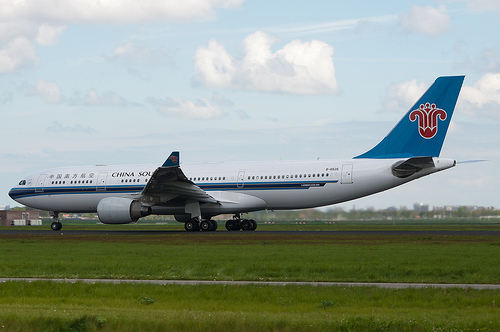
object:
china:
[111, 170, 138, 179]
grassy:
[3, 237, 499, 250]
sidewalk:
[0, 277, 496, 286]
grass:
[0, 237, 499, 329]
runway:
[4, 227, 499, 237]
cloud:
[193, 32, 335, 93]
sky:
[0, 0, 496, 74]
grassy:
[262, 220, 499, 231]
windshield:
[18, 179, 30, 187]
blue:
[63, 46, 107, 70]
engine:
[98, 197, 133, 225]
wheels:
[182, 220, 196, 232]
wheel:
[48, 221, 63, 228]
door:
[341, 164, 353, 183]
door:
[237, 171, 244, 189]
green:
[135, 293, 155, 304]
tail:
[352, 71, 471, 157]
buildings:
[7, 206, 28, 227]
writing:
[47, 172, 96, 179]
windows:
[317, 172, 328, 178]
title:
[113, 169, 153, 177]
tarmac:
[0, 212, 499, 241]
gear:
[52, 223, 63, 231]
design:
[409, 102, 447, 138]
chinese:
[49, 169, 62, 180]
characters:
[48, 172, 57, 178]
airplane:
[10, 75, 487, 230]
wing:
[139, 151, 215, 205]